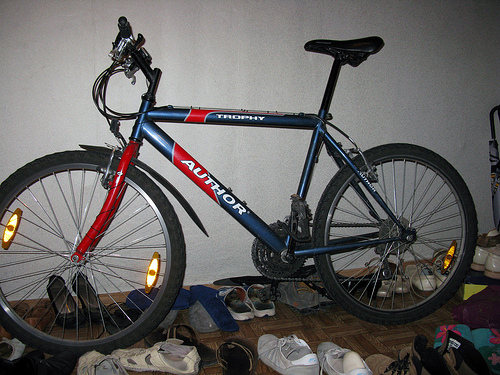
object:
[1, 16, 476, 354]
bicycle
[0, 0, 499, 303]
wall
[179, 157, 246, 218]
lettering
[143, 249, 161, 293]
reflector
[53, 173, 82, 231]
spokes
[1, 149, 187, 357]
wheel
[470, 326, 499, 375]
shoes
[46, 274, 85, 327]
heels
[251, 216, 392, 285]
chain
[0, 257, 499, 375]
floor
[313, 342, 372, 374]
shoes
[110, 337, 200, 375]
shoes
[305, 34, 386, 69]
seat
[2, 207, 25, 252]
reflector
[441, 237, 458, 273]
reflector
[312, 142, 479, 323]
wheel